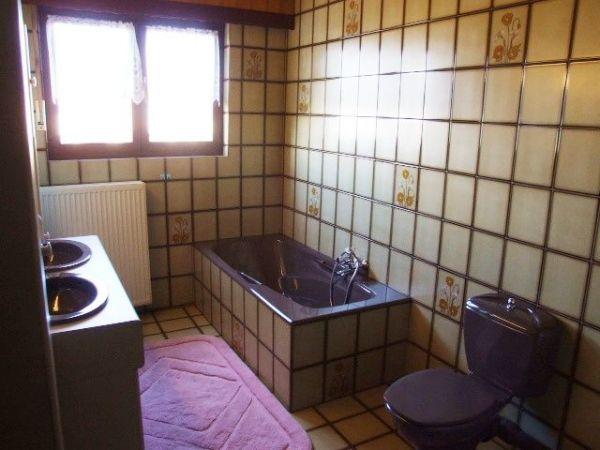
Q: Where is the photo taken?
A: In a bathroom.